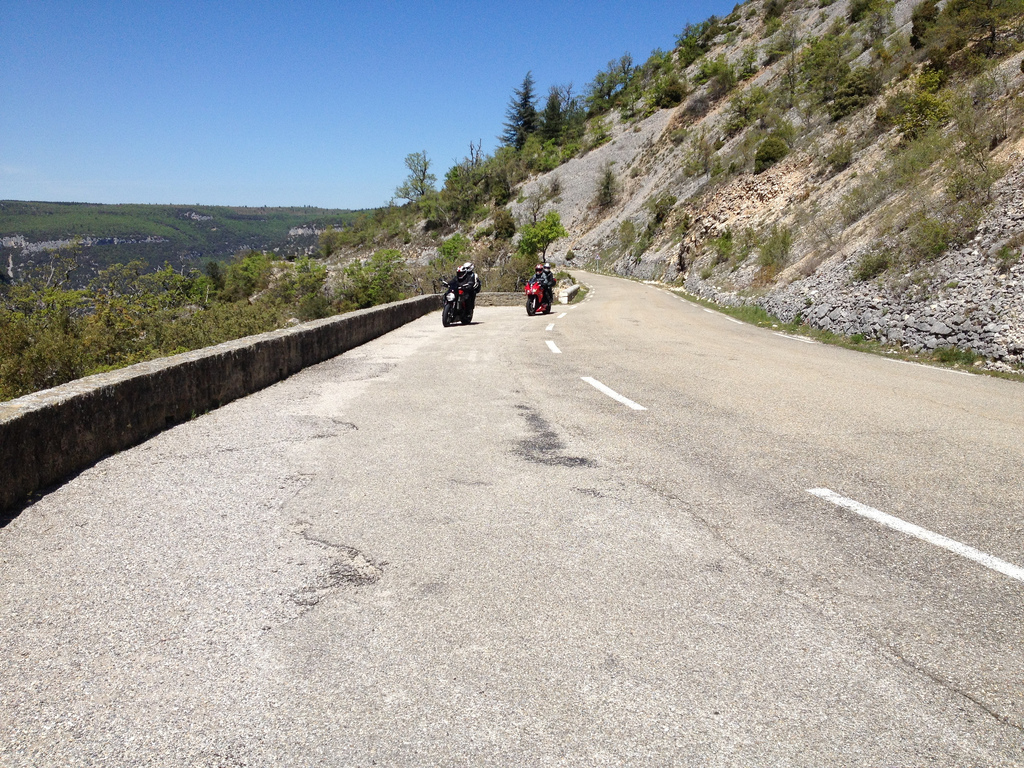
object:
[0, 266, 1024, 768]
asphalt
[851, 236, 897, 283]
bush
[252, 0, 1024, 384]
mountain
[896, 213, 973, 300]
bush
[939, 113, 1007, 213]
bush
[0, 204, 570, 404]
plants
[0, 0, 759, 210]
blue sky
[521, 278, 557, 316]
motorcycle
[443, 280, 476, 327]
motorcycle